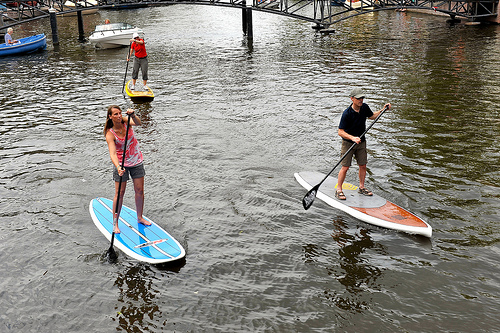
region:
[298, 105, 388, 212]
Black and white paddle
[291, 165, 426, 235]
Orange, gray and white board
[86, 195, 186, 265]
Blue, black and white board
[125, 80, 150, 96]
Yellow board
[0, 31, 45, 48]
Blue boat carrying a person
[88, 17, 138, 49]
White boat in background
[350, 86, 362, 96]
Gray baseball cap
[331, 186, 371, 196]
Pair of tan sandals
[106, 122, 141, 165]
Orange and white tank top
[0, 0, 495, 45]
Metal bridge in background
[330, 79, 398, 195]
A man sailing with a skateboard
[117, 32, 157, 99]
A man sailing with a skateboard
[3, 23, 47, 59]
A man in a blue boat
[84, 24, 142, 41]
A white sea ship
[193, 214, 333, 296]
A dark water surface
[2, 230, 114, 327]
A dark water surface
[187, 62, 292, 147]
A dark water surface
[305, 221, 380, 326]
A human reflection in water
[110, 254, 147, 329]
A human reflection in water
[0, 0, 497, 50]
bottom of bridge frame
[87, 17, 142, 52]
front of white boat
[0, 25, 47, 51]
person sitting in blue boat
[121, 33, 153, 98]
person standing on paddleboard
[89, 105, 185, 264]
woman on blue paddleboard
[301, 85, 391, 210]
man with paddle in hand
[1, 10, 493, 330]
reflection on water surface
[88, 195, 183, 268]
blue and white paddleboard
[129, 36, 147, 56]
red shirt on body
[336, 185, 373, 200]
sandals on man's feet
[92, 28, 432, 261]
three people paddle boarding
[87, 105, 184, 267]
woman on a blue paddle board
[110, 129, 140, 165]
pink floral shirt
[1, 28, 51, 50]
man in blue boat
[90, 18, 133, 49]
white motor boat under a bridge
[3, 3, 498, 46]
long metal bridge over the water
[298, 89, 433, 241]
man in a black t-shirt and brown shorts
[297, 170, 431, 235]
gray and orange paddle board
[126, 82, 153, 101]
yellow paddle board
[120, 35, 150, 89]
person in a red shirt on yellow paddle boad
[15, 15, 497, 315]
The people are standing on surfboards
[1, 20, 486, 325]
The people are paddling down a river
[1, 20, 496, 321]
The people are using their oars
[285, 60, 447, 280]
The man is standing up straight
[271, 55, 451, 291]
A man is using his oar to paddle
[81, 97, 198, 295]
A woman is going down the river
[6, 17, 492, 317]
The people are enjoying their day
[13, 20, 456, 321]
The people are on their day off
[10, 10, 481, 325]
The people are having lots of fun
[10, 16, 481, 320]
The people are using their balance